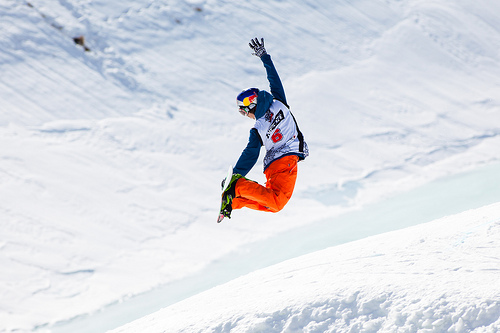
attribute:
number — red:
[268, 126, 287, 145]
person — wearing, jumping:
[209, 35, 311, 225]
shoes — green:
[214, 171, 244, 222]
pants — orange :
[234, 153, 299, 219]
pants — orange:
[214, 140, 372, 257]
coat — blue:
[226, 53, 310, 180]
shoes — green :
[226, 172, 263, 229]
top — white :
[249, 94, 311, 172]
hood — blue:
[245, 93, 291, 121]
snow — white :
[23, 30, 236, 212]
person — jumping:
[162, 40, 369, 232]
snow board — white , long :
[216, 165, 235, 226]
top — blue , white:
[223, 89, 335, 176]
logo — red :
[241, 95, 260, 107]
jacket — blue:
[218, 48, 310, 216]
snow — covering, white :
[0, 0, 498, 330]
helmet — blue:
[232, 88, 274, 120]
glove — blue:
[249, 36, 267, 57]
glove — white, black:
[246, 34, 265, 57]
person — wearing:
[221, 28, 307, 226]